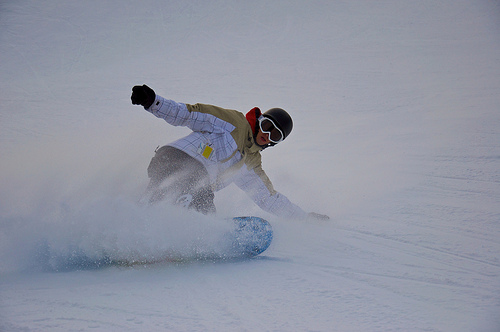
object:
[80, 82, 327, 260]
snowboarder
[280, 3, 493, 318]
slope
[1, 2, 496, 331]
snow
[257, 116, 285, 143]
goggles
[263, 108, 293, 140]
helmet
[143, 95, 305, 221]
jacket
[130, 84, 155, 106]
glove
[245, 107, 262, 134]
hood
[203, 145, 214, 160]
tag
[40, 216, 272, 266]
snowboard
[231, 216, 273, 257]
tip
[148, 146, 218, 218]
pants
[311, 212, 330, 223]
hand